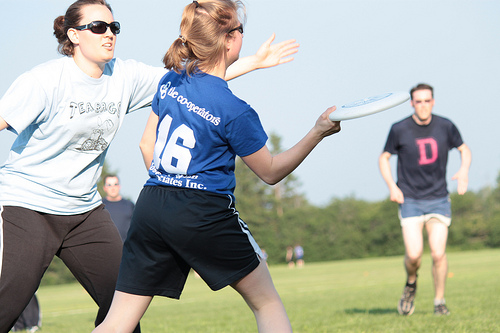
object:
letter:
[416, 138, 438, 165]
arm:
[119, 56, 258, 90]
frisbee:
[328, 92, 412, 121]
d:
[416, 138, 437, 166]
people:
[294, 242, 306, 267]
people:
[284, 246, 296, 268]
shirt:
[382, 111, 464, 196]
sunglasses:
[74, 21, 121, 34]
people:
[0, 0, 300, 331]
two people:
[275, 235, 318, 271]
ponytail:
[53, 15, 73, 56]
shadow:
[331, 300, 432, 316]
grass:
[37, 255, 497, 330]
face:
[413, 90, 433, 119]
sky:
[243, 2, 498, 121]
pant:
[0, 206, 141, 333]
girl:
[88, 0, 342, 333]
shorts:
[111, 182, 265, 301]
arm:
[215, 104, 321, 185]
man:
[378, 84, 472, 315]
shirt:
[142, 65, 267, 195]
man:
[97, 173, 135, 241]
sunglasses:
[414, 99, 432, 103]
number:
[153, 114, 196, 175]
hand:
[315, 105, 341, 137]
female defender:
[0, 1, 300, 333]